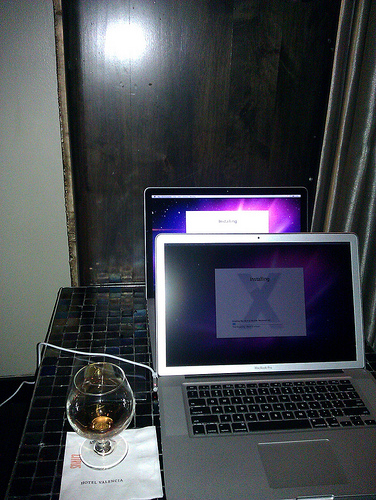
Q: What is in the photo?
A: Laptops.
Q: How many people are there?
A: None.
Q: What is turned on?
A: Laptop.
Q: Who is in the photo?
A: No one.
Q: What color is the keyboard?
A: Black and white.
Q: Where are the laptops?
A: On a table.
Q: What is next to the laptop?
A: Glass.